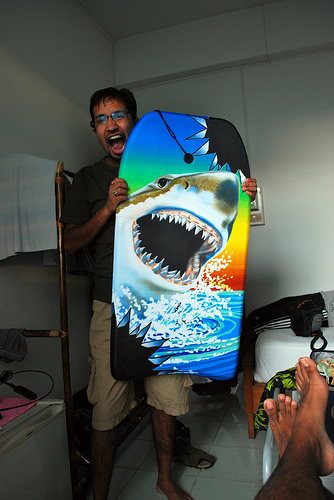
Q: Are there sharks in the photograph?
A: Yes, there is a shark.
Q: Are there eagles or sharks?
A: Yes, there is a shark.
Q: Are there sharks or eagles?
A: Yes, there is a shark.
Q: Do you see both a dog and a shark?
A: No, there is a shark but no dogs.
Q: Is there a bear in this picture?
A: No, there are no bears.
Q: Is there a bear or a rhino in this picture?
A: No, there are no bears or rhinos.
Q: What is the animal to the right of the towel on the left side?
A: The animal is a shark.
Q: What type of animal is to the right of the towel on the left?
A: The animal is a shark.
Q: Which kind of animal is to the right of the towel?
A: The animal is a shark.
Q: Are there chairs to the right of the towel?
A: No, there is a shark to the right of the towel.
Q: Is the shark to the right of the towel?
A: Yes, the shark is to the right of the towel.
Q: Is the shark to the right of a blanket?
A: No, the shark is to the right of the towel.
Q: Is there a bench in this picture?
A: No, there are no benches.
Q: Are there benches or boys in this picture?
A: No, there are no benches or boys.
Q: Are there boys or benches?
A: No, there are no benches or boys.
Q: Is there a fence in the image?
A: No, there are no fences.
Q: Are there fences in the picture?
A: No, there are no fences.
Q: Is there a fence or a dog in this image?
A: No, there are no fences or dogs.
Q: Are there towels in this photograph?
A: Yes, there is a towel.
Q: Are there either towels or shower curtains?
A: Yes, there is a towel.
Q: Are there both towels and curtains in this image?
A: No, there is a towel but no curtains.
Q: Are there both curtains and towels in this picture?
A: No, there is a towel but no curtains.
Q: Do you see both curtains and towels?
A: No, there is a towel but no curtains.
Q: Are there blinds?
A: No, there are no blinds.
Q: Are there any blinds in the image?
A: No, there are no blinds.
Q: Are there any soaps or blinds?
A: No, there are no blinds or soaps.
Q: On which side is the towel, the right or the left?
A: The towel is on the left of the image.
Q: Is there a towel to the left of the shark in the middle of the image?
A: Yes, there is a towel to the left of the shark.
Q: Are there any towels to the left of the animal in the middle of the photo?
A: Yes, there is a towel to the left of the shark.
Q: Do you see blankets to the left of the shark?
A: No, there is a towel to the left of the shark.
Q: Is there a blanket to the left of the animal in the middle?
A: No, there is a towel to the left of the shark.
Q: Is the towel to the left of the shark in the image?
A: Yes, the towel is to the left of the shark.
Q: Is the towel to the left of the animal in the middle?
A: Yes, the towel is to the left of the shark.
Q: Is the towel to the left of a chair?
A: No, the towel is to the left of the shark.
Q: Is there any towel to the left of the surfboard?
A: Yes, there is a towel to the left of the surfboard.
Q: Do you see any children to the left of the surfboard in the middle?
A: No, there is a towel to the left of the surfboard.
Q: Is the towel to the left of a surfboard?
A: Yes, the towel is to the left of a surfboard.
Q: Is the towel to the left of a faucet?
A: No, the towel is to the left of a surfboard.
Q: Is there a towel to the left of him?
A: Yes, there is a towel to the left of the man.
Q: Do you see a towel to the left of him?
A: Yes, there is a towel to the left of the man.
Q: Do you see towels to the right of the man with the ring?
A: No, the towel is to the left of the man.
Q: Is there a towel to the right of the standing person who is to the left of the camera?
A: No, the towel is to the left of the man.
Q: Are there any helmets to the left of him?
A: No, there is a towel to the left of the man.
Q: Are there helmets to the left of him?
A: No, there is a towel to the left of the man.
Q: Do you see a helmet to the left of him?
A: No, there is a towel to the left of the man.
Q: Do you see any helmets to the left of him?
A: No, there is a towel to the left of the man.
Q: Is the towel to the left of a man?
A: Yes, the towel is to the left of a man.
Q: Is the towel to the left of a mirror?
A: No, the towel is to the left of a man.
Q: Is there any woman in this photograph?
A: No, there are no women.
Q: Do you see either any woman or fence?
A: No, there are no women or fences.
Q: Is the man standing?
A: Yes, the man is standing.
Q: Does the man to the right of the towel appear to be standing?
A: Yes, the man is standing.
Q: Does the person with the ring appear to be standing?
A: Yes, the man is standing.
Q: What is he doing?
A: The man is standing.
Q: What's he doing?
A: The man is standing.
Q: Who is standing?
A: The man is standing.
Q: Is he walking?
A: No, the man is standing.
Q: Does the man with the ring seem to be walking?
A: No, the man is standing.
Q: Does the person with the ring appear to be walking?
A: No, the man is standing.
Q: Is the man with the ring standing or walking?
A: The man is standing.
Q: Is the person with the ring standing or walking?
A: The man is standing.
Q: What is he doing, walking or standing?
A: The man is standing.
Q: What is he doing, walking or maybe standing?
A: The man is standing.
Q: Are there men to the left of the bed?
A: Yes, there is a man to the left of the bed.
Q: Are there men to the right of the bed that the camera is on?
A: No, the man is to the left of the bed.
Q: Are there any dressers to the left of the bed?
A: No, there is a man to the left of the bed.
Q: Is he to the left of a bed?
A: Yes, the man is to the left of a bed.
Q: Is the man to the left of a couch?
A: No, the man is to the left of a bed.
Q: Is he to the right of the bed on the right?
A: No, the man is to the left of the bed.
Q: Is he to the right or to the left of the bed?
A: The man is to the left of the bed.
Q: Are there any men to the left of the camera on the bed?
A: Yes, there is a man to the left of the camera.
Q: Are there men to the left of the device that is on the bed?
A: Yes, there is a man to the left of the camera.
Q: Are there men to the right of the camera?
A: No, the man is to the left of the camera.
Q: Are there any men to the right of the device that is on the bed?
A: No, the man is to the left of the camera.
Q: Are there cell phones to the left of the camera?
A: No, there is a man to the left of the camera.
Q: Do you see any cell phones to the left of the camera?
A: No, there is a man to the left of the camera.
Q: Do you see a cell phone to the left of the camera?
A: No, there is a man to the left of the camera.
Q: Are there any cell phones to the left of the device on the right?
A: No, there is a man to the left of the camera.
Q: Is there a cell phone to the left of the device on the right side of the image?
A: No, there is a man to the left of the camera.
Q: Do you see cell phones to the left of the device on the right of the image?
A: No, there is a man to the left of the camera.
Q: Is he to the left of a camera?
A: Yes, the man is to the left of a camera.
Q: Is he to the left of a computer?
A: No, the man is to the left of a camera.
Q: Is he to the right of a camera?
A: No, the man is to the left of a camera.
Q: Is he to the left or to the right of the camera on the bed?
A: The man is to the left of the camera.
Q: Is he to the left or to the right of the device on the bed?
A: The man is to the left of the camera.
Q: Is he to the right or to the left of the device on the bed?
A: The man is to the left of the camera.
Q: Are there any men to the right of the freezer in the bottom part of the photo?
A: Yes, there is a man to the right of the freezer.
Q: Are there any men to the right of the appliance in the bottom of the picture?
A: Yes, there is a man to the right of the freezer.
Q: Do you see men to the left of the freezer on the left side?
A: No, the man is to the right of the refrigerator.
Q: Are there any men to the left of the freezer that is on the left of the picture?
A: No, the man is to the right of the refrigerator.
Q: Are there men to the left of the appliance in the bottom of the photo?
A: No, the man is to the right of the refrigerator.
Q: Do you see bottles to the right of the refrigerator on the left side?
A: No, there is a man to the right of the fridge.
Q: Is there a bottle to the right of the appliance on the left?
A: No, there is a man to the right of the fridge.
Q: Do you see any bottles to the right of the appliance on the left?
A: No, there is a man to the right of the fridge.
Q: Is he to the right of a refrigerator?
A: Yes, the man is to the right of a refrigerator.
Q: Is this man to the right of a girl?
A: No, the man is to the right of a refrigerator.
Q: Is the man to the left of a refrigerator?
A: No, the man is to the right of a refrigerator.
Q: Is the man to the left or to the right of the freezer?
A: The man is to the right of the freezer.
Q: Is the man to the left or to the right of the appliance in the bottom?
A: The man is to the right of the freezer.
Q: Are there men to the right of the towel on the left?
A: Yes, there is a man to the right of the towel.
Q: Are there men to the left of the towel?
A: No, the man is to the right of the towel.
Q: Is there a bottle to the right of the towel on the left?
A: No, there is a man to the right of the towel.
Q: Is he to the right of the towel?
A: Yes, the man is to the right of the towel.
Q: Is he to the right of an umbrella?
A: No, the man is to the right of the towel.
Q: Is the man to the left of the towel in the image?
A: No, the man is to the right of the towel.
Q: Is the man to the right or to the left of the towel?
A: The man is to the right of the towel.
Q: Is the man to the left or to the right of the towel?
A: The man is to the right of the towel.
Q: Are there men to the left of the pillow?
A: Yes, there is a man to the left of the pillow.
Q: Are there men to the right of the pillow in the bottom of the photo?
A: No, the man is to the left of the pillow.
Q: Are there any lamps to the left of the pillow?
A: No, there is a man to the left of the pillow.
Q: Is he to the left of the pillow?
A: Yes, the man is to the left of the pillow.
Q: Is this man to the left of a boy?
A: No, the man is to the left of the pillow.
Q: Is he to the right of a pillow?
A: No, the man is to the left of a pillow.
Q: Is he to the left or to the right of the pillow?
A: The man is to the left of the pillow.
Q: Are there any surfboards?
A: Yes, there is a surfboard.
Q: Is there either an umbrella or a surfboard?
A: Yes, there is a surfboard.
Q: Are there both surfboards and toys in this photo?
A: No, there is a surfboard but no toys.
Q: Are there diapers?
A: No, there are no diapers.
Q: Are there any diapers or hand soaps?
A: No, there are no diapers or hand soaps.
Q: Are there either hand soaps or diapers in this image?
A: No, there are no diapers or hand soaps.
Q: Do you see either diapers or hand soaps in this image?
A: No, there are no diapers or hand soaps.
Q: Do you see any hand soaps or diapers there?
A: No, there are no diapers or hand soaps.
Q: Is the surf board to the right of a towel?
A: Yes, the surf board is to the right of a towel.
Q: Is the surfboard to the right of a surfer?
A: No, the surfboard is to the right of a towel.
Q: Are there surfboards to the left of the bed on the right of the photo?
A: Yes, there is a surfboard to the left of the bed.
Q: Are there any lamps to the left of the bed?
A: No, there is a surfboard to the left of the bed.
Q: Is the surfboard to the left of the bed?
A: Yes, the surfboard is to the left of the bed.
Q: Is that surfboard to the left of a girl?
A: No, the surfboard is to the left of the bed.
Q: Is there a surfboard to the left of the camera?
A: Yes, there is a surfboard to the left of the camera.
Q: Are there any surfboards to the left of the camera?
A: Yes, there is a surfboard to the left of the camera.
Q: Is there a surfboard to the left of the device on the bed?
A: Yes, there is a surfboard to the left of the camera.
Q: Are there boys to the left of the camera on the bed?
A: No, there is a surfboard to the left of the camera.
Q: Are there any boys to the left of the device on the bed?
A: No, there is a surfboard to the left of the camera.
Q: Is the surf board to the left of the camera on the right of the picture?
A: Yes, the surf board is to the left of the camera.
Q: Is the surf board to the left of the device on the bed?
A: Yes, the surf board is to the left of the camera.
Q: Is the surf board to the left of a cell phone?
A: No, the surf board is to the left of the camera.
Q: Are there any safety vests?
A: No, there are no safety vests.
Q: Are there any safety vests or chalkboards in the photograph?
A: No, there are no safety vests or chalkboards.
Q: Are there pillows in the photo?
A: Yes, there is a pillow.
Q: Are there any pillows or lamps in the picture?
A: Yes, there is a pillow.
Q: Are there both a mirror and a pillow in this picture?
A: No, there is a pillow but no mirrors.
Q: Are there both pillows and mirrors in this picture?
A: No, there is a pillow but no mirrors.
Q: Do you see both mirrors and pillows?
A: No, there is a pillow but no mirrors.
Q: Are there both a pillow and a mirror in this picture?
A: No, there is a pillow but no mirrors.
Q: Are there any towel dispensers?
A: No, there are no towel dispensers.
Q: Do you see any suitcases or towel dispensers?
A: No, there are no towel dispensers or suitcases.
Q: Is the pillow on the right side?
A: Yes, the pillow is on the right of the image.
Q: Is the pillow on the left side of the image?
A: No, the pillow is on the right of the image.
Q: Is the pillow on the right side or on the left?
A: The pillow is on the right of the image.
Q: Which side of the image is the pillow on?
A: The pillow is on the right of the image.